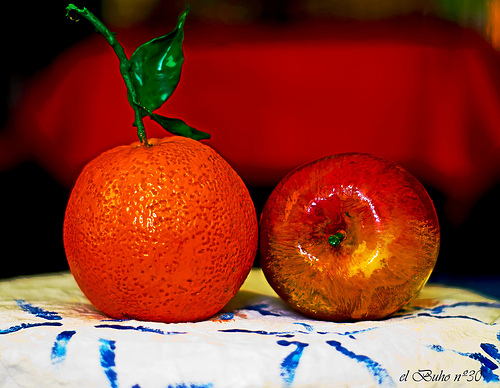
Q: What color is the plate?
A: White.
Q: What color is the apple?
A: Red.